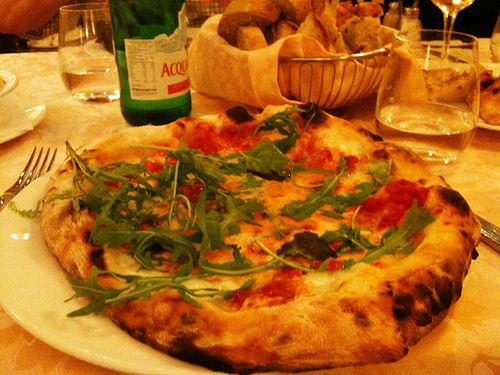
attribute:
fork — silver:
[2, 142, 59, 203]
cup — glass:
[369, 27, 484, 167]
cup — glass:
[377, 34, 468, 167]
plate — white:
[1, 160, 223, 372]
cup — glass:
[352, 21, 487, 219]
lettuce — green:
[234, 131, 298, 178]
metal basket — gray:
[197, 11, 395, 111]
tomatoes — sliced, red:
[136, 117, 421, 314]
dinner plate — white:
[1, 115, 315, 373]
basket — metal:
[192, 15, 422, 110]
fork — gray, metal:
[0, 128, 70, 234]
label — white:
[112, 37, 197, 114]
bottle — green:
[105, 0, 190, 127]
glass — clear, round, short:
[378, 24, 488, 182]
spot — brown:
[388, 253, 462, 338]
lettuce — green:
[93, 213, 195, 253]